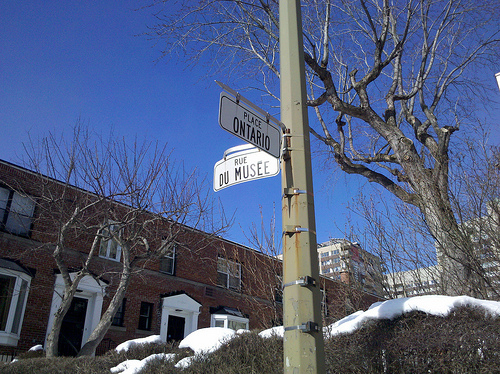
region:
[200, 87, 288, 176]
Road signage in the photo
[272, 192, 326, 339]
A pole on the photo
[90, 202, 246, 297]
A building in the photo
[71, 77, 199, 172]
Blue skies in the photo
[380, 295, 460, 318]
Snow cover in the photo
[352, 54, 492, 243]
Tree in the picture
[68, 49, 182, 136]
Clear skies in the picture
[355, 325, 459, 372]
Dry grass in the photo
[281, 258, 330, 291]
Metallic braces on the pole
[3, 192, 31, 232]
Window on the building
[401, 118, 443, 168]
branch of the tree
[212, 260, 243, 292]
window on the building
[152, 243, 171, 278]
window on the building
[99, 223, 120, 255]
window on the building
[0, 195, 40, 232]
window on the building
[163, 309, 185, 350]
window on the building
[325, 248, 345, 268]
window on the building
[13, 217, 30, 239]
window on the building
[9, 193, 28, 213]
window on the building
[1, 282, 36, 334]
window on the building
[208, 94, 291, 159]
white sign with black lettering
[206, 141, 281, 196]
white sign with black lettering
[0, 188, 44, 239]
window on a red brick building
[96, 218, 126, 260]
window on a red brick building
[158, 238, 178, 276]
window on a red brick building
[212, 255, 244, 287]
window on a red brick building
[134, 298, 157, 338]
window on a red brick building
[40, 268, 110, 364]
black door with a white frame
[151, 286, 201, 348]
black door with a white frame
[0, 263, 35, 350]
window on a red brick building